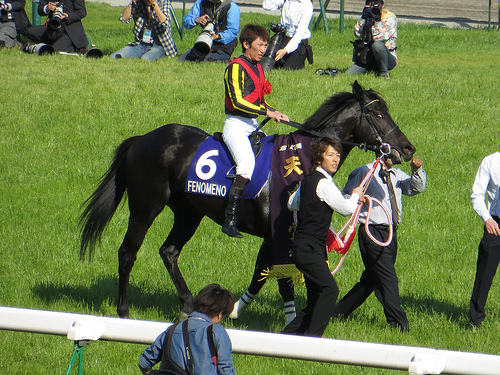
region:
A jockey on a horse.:
[82, 21, 417, 327]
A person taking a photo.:
[347, 0, 399, 80]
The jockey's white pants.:
[221, 112, 263, 177]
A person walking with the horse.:
[283, 137, 370, 338]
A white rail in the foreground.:
[0, 303, 499, 374]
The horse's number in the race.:
[183, 145, 228, 198]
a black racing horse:
[70, 19, 442, 346]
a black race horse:
[58, 22, 439, 331]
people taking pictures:
[21, 1, 418, 83]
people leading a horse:
[286, 92, 456, 325]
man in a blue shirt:
[136, 260, 256, 374]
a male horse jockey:
[206, 22, 320, 262]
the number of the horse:
[176, 113, 338, 241]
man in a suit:
[345, 133, 439, 333]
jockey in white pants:
[216, 18, 312, 213]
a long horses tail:
[58, 99, 171, 289]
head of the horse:
[314, 74, 441, 176]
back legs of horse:
[89, 200, 222, 299]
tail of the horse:
[45, 131, 146, 247]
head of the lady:
[171, 273, 246, 345]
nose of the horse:
[375, 128, 430, 180]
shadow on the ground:
[23, 260, 111, 320]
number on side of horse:
[176, 137, 232, 202]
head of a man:
[300, 125, 355, 189]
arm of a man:
[391, 146, 436, 210]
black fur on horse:
[128, 125, 198, 185]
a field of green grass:
[0, 0, 499, 374]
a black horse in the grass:
[77, 78, 417, 326]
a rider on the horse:
[221, 23, 288, 238]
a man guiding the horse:
[280, 136, 362, 337]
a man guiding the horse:
[330, 151, 425, 331]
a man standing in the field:
[467, 150, 499, 330]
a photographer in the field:
[343, 0, 396, 77]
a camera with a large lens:
[257, 22, 285, 71]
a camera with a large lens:
[191, 16, 218, 56]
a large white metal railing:
[0, 305, 499, 373]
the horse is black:
[97, 76, 437, 317]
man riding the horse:
[178, 20, 426, 259]